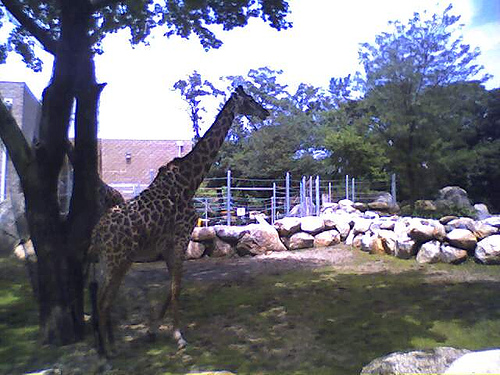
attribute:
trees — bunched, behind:
[173, 3, 493, 209]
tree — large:
[5, 8, 165, 355]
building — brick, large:
[2, 75, 195, 221]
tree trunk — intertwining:
[12, 94, 100, 365]